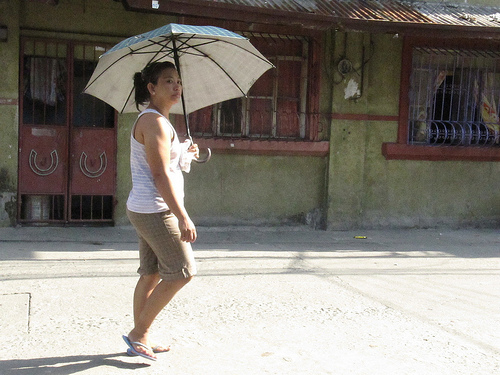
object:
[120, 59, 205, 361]
woman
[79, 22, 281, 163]
umbrella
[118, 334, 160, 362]
flip flop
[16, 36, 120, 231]
door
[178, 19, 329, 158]
window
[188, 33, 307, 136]
metal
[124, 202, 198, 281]
pants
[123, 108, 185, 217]
tank top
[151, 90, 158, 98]
earring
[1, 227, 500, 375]
sidewalk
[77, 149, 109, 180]
horse shoe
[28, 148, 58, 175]
horse shoe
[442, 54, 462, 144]
bar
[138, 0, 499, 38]
roof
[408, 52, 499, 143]
curtain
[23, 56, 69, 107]
curtain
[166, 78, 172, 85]
eye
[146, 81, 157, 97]
ear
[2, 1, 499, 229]
building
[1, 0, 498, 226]
wall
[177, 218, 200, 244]
right hand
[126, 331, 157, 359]
right foot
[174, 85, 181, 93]
nose